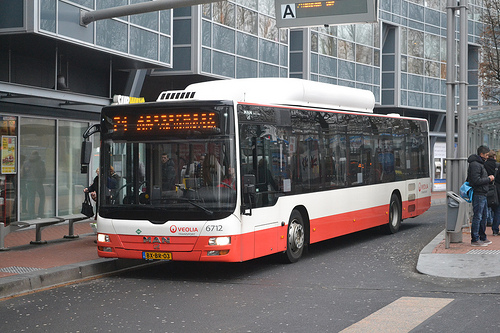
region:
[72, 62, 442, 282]
bus on a street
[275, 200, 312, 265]
front wheel of a vehicle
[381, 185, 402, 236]
rear wheel of a vehicle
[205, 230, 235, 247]
front headlight of a vehicle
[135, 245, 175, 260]
front licence plate of a vehicle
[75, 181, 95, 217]
black purse in a persons hand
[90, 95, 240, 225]
front windshield of a vehicle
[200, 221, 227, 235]
number on the front of a vehicle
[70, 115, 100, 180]
side rear view mirror of a vehicle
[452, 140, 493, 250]
person with a blue bag standing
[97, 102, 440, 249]
A bus parked near the bus stop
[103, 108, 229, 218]
Front side glass with wiper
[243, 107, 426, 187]
Glass windows of the bus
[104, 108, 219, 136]
Orange color LED name board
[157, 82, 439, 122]
Roof of the bus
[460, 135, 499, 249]
A man standing in the side walk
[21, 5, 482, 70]
Buildings near the bus stop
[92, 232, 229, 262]
Head lights with side indicator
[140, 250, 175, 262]
A yellow color number plate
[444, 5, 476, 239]
A metal post in the side walk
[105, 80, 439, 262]
red and white bus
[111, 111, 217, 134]
destination sign on bus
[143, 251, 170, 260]
yellow and black license plate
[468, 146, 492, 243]
man standing on corner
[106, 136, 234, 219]
glass windshield on bus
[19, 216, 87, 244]
grey concrete benches on sidewalk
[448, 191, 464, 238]
grey metal trash can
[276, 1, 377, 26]
grey sign on pole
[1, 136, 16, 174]
sign taped in window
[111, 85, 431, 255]
bus parked at sidewalk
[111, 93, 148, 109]
Subway Restaurant sign in background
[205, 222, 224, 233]
bus number 6712 on front of bus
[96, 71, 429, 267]
large red and white passenger bus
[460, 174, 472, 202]
blue backpack on shoulder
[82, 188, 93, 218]
black purse with handles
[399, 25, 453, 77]
trees reflected in windows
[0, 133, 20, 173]
Subway menu sign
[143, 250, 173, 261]
orange license plate on bus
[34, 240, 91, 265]
brick inlay on sidewalk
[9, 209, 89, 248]
bus stop benches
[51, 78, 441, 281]
bus on the street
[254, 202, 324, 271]
tire on the car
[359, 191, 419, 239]
back tire of bus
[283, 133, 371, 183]
windows on the bus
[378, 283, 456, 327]
white line on street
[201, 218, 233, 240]
number on the bus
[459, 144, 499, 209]
people on the sidewalk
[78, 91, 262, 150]
top of the bus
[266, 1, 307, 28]
letter on top of the photo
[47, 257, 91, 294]
curb next to the street